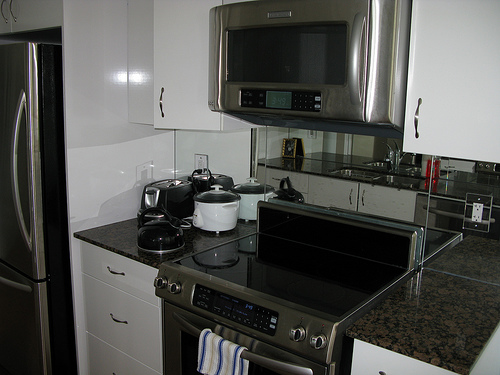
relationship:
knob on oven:
[168, 282, 183, 298] [168, 206, 438, 372]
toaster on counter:
[135, 172, 199, 227] [65, 176, 291, 273]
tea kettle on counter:
[134, 206, 199, 258] [73, 197, 333, 287]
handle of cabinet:
[413, 98, 423, 139] [393, 1, 498, 169]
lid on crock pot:
[194, 182, 240, 203] [177, 178, 252, 240]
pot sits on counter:
[138, 219, 178, 247] [76, 185, 256, 264]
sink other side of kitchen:
[331, 167, 381, 179] [1, 1, 498, 373]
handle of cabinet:
[154, 82, 170, 123] [149, 0, 256, 137]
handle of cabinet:
[154, 82, 170, 123] [66, 236, 201, 309]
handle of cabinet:
[413, 98, 423, 139] [66, 236, 201, 309]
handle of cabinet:
[106, 265, 126, 275] [66, 236, 201, 309]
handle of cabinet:
[107, 313, 128, 326] [66, 236, 201, 309]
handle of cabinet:
[99, 304, 129, 338] [68, 196, 495, 373]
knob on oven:
[308, 330, 329, 350] [151, 194, 427, 374]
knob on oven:
[282, 316, 334, 349] [167, 214, 352, 373]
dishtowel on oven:
[186, 326, 254, 374] [151, 194, 427, 374]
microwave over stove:
[209, 0, 411, 137] [159, 198, 392, 373]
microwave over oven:
[209, 0, 411, 137] [151, 194, 427, 374]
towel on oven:
[190, 325, 252, 373] [151, 194, 427, 374]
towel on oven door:
[190, 325, 252, 373] [146, 258, 332, 372]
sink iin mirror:
[330, 167, 421, 190] [250, 120, 498, 237]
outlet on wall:
[465, 199, 487, 224] [418, 159, 499, 254]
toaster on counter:
[135, 172, 199, 227] [353, 264, 498, 370]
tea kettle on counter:
[134, 206, 199, 258] [83, 218, 220, 260]